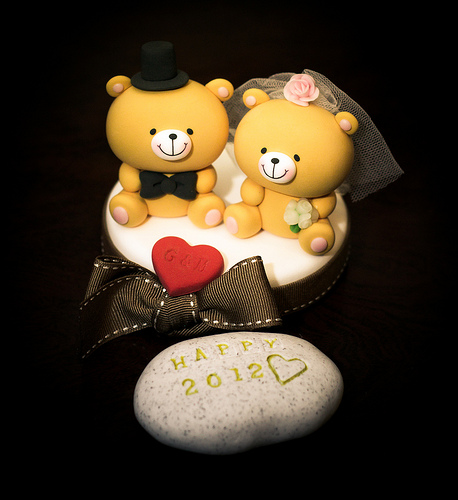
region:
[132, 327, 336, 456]
round smooth gray stone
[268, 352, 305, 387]
green heart etched in stone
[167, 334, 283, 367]
word Happy etched in stone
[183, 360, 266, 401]
numbers 2012 etched in stone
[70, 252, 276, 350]
black ribbon with white stitch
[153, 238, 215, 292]
red clay heart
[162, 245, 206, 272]
G and M written in heart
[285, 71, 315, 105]
small pink rose on bear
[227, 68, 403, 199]
small white veil of bear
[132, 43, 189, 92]
black top hat of bear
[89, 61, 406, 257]
Two wedding bears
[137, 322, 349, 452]
A memorabilia stone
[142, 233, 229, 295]
There is a red heart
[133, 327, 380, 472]
the stone is white with spots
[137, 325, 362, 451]
the stone has a heart on it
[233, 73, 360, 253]
the bear has two flowers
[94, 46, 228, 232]
The bear has a hat and tie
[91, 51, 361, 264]
The bears are smiling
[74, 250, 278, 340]
There is a brown bow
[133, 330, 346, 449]
The stone says happy 2012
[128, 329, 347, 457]
stone engraved with words HAPPY 2012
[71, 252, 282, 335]
black ribbon with white stitching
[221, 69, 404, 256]
tiny teddy bear bride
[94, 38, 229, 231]
tiny teddy bear groom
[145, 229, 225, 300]
red heart engraved with initials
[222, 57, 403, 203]
white faux veil with pink flower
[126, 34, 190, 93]
tiny black top hat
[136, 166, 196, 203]
black bow tie on teddy bear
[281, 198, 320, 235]
white and green floral bouquet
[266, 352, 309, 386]
green traced heart on stone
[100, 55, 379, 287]
two yellow bears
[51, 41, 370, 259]
A bride and groom bear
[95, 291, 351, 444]
A rock with a date on it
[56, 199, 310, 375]
A black bow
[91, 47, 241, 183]
The head of a groom bear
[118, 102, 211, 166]
The face of a groom bear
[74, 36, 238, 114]
The ears of a groom bear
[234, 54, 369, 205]
The head of a bride bear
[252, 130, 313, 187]
The face of a bride bear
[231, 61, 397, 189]
The veil of a bride bear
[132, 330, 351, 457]
grey stone with anniversary message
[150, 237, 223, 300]
small red monogrammed heart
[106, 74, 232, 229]
small orange teddy bear groom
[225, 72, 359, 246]
small orange teddy bear bride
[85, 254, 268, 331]
dark brown ribbon bow with white stitching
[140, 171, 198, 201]
small black bow-tie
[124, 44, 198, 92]
small black tophat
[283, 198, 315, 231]
tiny bouquet of white flowers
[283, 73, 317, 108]
small pink rose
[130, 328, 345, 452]
rock with heart engraved on it